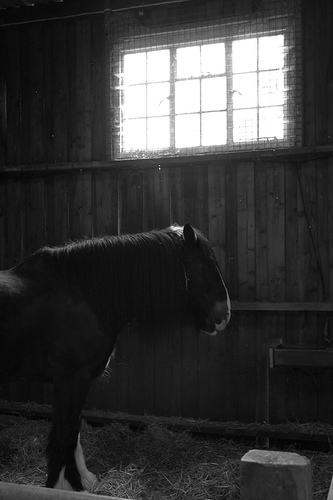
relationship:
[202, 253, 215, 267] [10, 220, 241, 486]
eye on animal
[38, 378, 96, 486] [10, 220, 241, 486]
leg on animal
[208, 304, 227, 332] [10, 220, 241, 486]
nose on animal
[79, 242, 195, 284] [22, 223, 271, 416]
mane on horse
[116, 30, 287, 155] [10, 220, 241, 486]
windows above animal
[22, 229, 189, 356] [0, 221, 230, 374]
long mane on horse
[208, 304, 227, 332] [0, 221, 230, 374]
nose on horse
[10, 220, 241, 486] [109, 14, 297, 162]
animal standing under window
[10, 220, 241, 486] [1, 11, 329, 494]
animal in barn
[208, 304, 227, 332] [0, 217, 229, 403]
nose on horse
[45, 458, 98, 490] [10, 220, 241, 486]
feet on animal